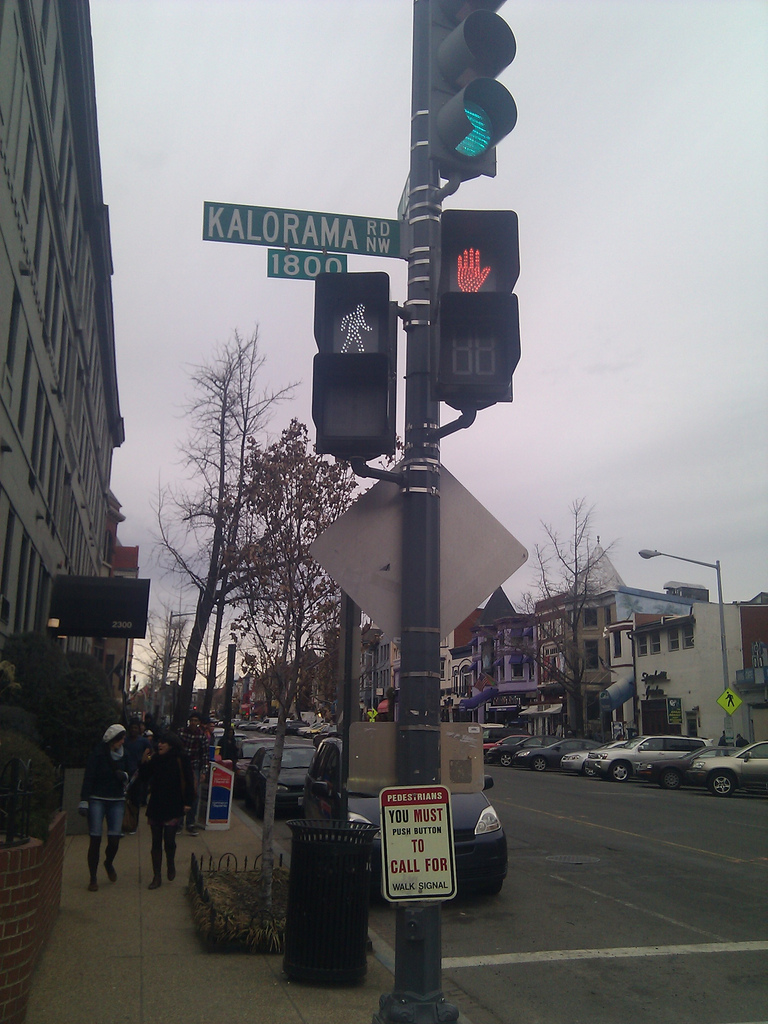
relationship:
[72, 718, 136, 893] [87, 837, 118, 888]
woman wearing boots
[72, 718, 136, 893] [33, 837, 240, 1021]
woman on sidewalk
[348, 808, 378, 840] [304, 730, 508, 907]
headlight on car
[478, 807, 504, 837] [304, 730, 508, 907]
headlight on car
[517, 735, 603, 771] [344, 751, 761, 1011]
car parked on street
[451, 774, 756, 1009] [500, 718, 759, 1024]
road dark grey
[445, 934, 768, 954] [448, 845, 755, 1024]
line on road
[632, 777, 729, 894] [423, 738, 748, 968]
lines on road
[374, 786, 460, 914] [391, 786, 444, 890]
sign with black and red lettering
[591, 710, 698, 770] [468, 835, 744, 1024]
suv parked on street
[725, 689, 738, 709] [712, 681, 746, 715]
person on sign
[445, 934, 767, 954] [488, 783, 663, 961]
line painted on street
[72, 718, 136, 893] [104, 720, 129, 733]
woman wearing hat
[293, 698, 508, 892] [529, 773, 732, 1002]
car parked on street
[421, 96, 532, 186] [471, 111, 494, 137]
traffic signal with light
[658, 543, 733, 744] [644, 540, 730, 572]
pole with street light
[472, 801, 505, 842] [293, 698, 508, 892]
headlight on car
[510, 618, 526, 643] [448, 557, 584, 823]
window on building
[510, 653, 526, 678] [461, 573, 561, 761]
window on building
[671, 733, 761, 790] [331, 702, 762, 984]
car on street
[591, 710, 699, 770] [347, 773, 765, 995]
suv on street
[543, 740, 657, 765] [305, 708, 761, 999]
car on street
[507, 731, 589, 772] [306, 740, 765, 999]
car on street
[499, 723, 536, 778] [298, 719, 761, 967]
car on street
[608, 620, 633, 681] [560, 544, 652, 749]
window on building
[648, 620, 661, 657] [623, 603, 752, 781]
window on building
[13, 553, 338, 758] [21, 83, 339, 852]
wall on side of building